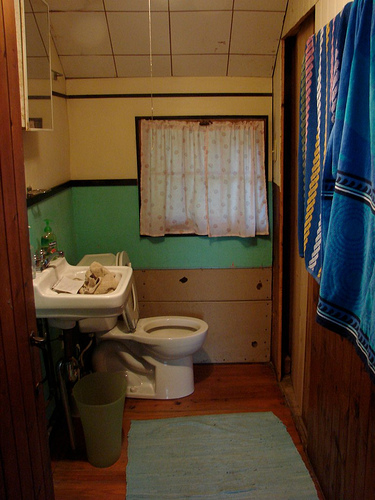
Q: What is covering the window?
A: A curtain.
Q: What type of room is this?
A: A bathroom.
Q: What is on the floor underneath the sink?
A: A garbage can.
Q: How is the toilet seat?
A: Up.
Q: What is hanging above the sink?
A: A mirror.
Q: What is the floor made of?
A: Wood.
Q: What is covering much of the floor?
A: A blue rug.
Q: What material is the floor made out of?
A: Wood.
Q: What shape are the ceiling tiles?
A: Square.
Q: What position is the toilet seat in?
A: The toilet seat is up.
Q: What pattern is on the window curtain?
A: Floral.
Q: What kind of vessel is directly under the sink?
A: Trash can.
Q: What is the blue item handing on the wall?
A: Towel.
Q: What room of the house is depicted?
A: Bathroom.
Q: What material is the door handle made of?
A: Metal.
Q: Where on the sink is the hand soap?
A: To the right of the faucet.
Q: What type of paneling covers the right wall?
A: Wood.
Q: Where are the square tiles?
A: On the ceiling.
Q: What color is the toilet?
A: White.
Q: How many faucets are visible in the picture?
A: One.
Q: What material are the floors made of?
A: Wood.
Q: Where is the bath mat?
A: On the floor.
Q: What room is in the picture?
A: Bathroom.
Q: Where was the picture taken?
A: In a bathroom.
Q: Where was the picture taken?
A: A bathroom.